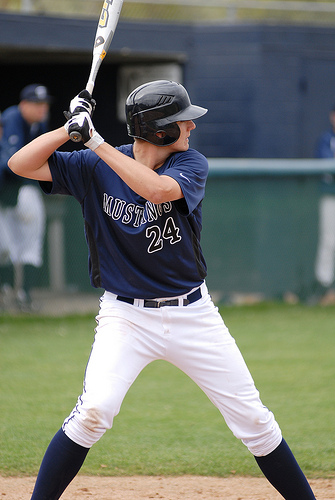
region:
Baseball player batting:
[5, 78, 312, 499]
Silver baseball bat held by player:
[62, 0, 123, 142]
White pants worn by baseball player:
[60, 281, 282, 454]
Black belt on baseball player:
[111, 288, 206, 310]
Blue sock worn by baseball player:
[28, 429, 91, 498]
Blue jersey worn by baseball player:
[47, 144, 210, 297]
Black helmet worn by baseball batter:
[123, 74, 206, 149]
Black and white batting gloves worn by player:
[64, 88, 102, 149]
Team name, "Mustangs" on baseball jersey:
[94, 189, 166, 224]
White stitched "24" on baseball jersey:
[143, 216, 182, 254]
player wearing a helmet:
[109, 63, 220, 142]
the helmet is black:
[104, 65, 212, 140]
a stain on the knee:
[44, 390, 114, 450]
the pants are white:
[44, 299, 287, 461]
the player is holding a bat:
[29, 1, 132, 187]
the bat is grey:
[60, 0, 119, 126]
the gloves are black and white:
[54, 73, 109, 155]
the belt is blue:
[87, 282, 205, 312]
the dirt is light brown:
[78, 459, 240, 494]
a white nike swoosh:
[159, 163, 197, 198]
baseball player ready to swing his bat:
[11, 32, 313, 494]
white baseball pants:
[68, 289, 293, 467]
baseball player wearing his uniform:
[39, 74, 249, 319]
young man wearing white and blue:
[10, 45, 312, 480]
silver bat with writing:
[36, 0, 136, 158]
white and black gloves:
[52, 83, 116, 162]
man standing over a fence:
[1, 69, 77, 304]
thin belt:
[100, 279, 219, 312]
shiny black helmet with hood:
[123, 73, 208, 144]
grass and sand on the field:
[5, 335, 324, 498]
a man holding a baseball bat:
[50, 4, 232, 178]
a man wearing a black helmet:
[117, 66, 214, 157]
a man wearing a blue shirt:
[64, 77, 222, 304]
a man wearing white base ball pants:
[83, 121, 214, 495]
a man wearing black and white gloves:
[51, 74, 193, 154]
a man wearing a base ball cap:
[10, 71, 56, 149]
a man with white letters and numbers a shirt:
[78, 113, 230, 287]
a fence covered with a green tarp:
[209, 150, 316, 282]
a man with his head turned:
[122, 62, 226, 175]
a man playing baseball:
[34, 12, 251, 401]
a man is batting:
[16, 11, 319, 495]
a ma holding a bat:
[7, 1, 323, 496]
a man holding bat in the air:
[7, 1, 330, 499]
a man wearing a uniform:
[7, 9, 303, 499]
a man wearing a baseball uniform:
[25, 11, 325, 465]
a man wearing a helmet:
[68, 61, 223, 168]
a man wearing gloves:
[57, 67, 109, 151]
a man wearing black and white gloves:
[58, 85, 115, 153]